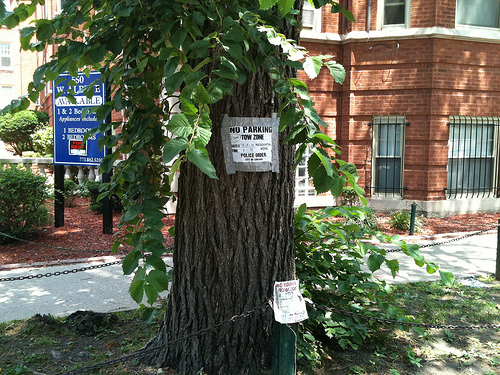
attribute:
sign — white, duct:
[212, 111, 290, 180]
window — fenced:
[362, 113, 498, 201]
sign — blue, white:
[49, 71, 110, 170]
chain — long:
[95, 295, 270, 352]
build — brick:
[343, 2, 496, 212]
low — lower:
[263, 265, 325, 375]